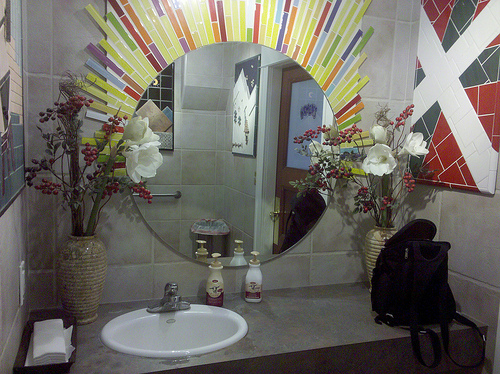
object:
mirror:
[123, 41, 342, 270]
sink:
[98, 301, 250, 359]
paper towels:
[24, 318, 76, 368]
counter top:
[13, 281, 488, 374]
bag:
[371, 218, 488, 369]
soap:
[204, 252, 225, 307]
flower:
[120, 140, 164, 184]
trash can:
[189, 217, 232, 259]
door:
[271, 61, 338, 254]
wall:
[18, 0, 423, 313]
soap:
[243, 250, 263, 303]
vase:
[50, 233, 108, 326]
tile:
[458, 57, 490, 90]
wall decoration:
[230, 52, 262, 158]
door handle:
[268, 208, 279, 222]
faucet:
[146, 281, 191, 315]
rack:
[12, 308, 78, 372]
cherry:
[409, 179, 416, 183]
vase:
[363, 223, 399, 291]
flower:
[122, 115, 161, 146]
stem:
[85, 154, 114, 237]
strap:
[440, 311, 487, 369]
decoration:
[70, 0, 375, 179]